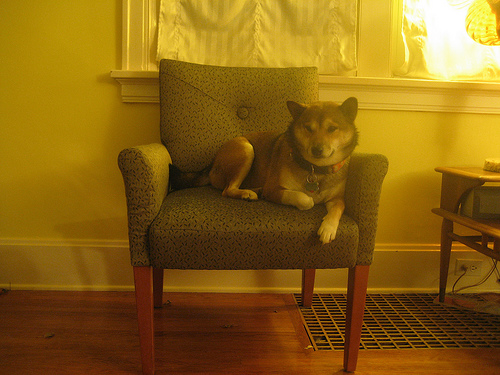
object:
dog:
[210, 96, 360, 245]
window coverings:
[155, 0, 357, 75]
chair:
[118, 58, 389, 375]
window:
[150, 0, 359, 77]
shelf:
[430, 207, 500, 261]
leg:
[439, 218, 454, 303]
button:
[237, 107, 248, 119]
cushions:
[149, 187, 359, 270]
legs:
[132, 267, 155, 374]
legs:
[301, 269, 316, 307]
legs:
[344, 266, 370, 372]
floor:
[0, 290, 500, 375]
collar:
[289, 144, 345, 193]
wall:
[0, 0, 500, 294]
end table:
[430, 166, 500, 303]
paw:
[296, 192, 314, 210]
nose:
[311, 146, 323, 156]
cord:
[455, 258, 482, 276]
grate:
[291, 293, 500, 353]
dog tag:
[305, 165, 319, 193]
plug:
[461, 264, 468, 271]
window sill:
[108, 69, 499, 114]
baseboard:
[0, 237, 500, 295]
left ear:
[341, 96, 358, 121]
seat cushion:
[159, 58, 320, 172]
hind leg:
[222, 136, 259, 202]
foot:
[222, 187, 258, 202]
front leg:
[317, 216, 341, 247]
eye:
[328, 126, 338, 133]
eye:
[306, 125, 313, 133]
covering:
[153, 0, 356, 76]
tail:
[169, 163, 212, 188]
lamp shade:
[464, 0, 499, 46]